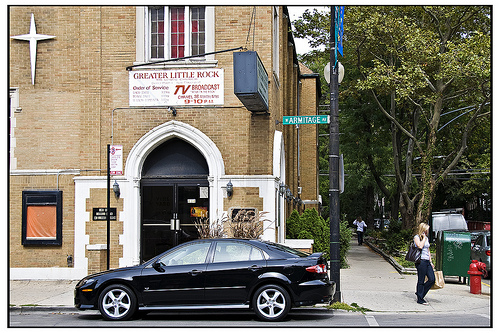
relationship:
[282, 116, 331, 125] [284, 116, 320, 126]
sign for armitage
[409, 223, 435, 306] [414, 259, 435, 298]
woman wearing jeans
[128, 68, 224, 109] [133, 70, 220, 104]
sign with words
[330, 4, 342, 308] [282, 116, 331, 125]
pole with sign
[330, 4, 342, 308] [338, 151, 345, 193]
pole with sign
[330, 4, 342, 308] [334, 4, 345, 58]
pole with sign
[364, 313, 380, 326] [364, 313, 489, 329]
stripe for crosswalk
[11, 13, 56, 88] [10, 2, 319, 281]
cross on building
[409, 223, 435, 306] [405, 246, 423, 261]
woman holding bag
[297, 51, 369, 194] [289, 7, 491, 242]
tree in background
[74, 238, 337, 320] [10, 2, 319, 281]
sedan in front of building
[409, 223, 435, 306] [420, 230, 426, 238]
woman talking on phone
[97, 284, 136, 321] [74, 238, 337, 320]
wheel of sedan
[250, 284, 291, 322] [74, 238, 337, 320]
wheel of sedan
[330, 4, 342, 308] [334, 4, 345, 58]
pole holding sign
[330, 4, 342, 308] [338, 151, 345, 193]
pole holding sign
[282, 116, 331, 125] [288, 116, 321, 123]
sign denoted armitage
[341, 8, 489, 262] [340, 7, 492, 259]
row of trees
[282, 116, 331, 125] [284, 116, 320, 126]
sign with armitage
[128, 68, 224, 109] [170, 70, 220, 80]
sign with little rock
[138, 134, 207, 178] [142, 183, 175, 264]
archway over door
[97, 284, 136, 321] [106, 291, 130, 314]
wheel with spokes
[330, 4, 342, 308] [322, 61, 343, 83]
pole with light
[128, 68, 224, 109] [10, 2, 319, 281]
sign on building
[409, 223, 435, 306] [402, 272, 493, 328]
woman on corner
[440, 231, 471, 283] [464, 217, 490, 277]
mailbox on street